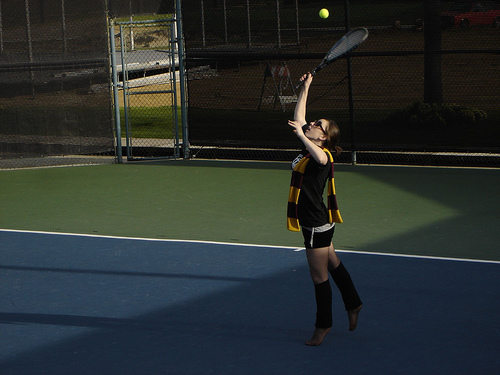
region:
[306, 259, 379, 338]
The woman is wearing leg warmers.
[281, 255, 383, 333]
The leg warmers are black.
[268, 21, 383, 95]
The woman is holding a racquet.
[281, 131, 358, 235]
The woman is wearing a scarf.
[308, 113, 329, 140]
The woman is wearing sunglasses.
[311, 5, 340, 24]
The tennis ball is yellow.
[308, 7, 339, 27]
The tennis ball is in mid air.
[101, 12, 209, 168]
There is a gate in the background.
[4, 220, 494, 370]
The tennis court is blue.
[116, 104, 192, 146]
The grass beyond the gate is green.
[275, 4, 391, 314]
the woman is holding a racket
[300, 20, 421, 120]
the racket is black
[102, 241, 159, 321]
the court is blue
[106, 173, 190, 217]
the outside court is green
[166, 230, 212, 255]
the line is white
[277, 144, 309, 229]
the scarf is stripes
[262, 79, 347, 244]
the woman is wearing stripes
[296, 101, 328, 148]
the woman is wearing eyeglasses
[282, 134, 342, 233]
the shirt is black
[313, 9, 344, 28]
the ball is yellow green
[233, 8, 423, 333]
The lady is hitting the tennis ball with a racquet.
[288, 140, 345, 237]
The lady have a gold and black scarf over her shoulder.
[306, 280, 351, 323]
The lady is wearing black leg warmers.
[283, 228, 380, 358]
The lady is on her tip toe.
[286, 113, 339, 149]
The lady is wearing sunglasses.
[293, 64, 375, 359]
The lady is practicing a dance move.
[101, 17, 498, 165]
A fence around the tennis court.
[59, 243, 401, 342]
The tennis court is blue.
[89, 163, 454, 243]
One end of the court is green.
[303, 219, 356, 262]
The lady is wearing black shorts.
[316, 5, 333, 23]
Tennis ball in the air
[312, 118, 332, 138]
Sunglasses on girl's face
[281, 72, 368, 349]
Girl playing tennis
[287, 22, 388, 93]
Tennis racket in girl's hand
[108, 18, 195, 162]
Gate to the tennis court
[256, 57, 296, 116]
Traffic sawhorse on lawn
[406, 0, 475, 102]
A tree outside the tennis court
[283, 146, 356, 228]
Yellow and brown scarf on girl's shoulder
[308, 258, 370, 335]
Black legwarmers on girl's legs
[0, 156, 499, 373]
blue and green tennis court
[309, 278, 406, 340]
black leg warmers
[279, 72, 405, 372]
woman standing on her toes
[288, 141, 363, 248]
black and yellow scarf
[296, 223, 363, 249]
black shorts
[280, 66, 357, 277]
white woman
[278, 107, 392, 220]
white woman wearing sunglasses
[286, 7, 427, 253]
white woman hitting a tennis ball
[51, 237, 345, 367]
blue section of the tennis court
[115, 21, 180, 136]
metal entrance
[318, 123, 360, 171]
brunette hair in a ponytail